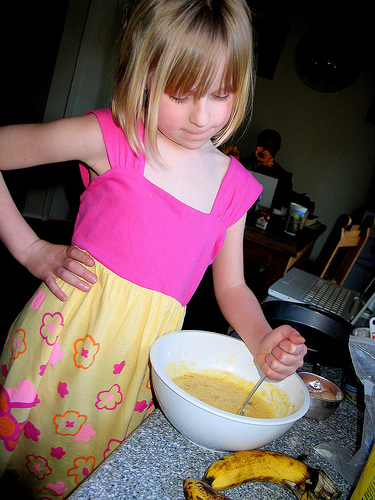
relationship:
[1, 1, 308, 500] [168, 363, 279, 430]
girl making food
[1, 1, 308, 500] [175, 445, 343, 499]
girl making food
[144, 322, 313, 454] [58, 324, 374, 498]
bowl on counter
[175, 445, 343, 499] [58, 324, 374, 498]
food on counter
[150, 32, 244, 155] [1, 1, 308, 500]
face of girl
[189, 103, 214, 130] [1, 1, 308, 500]
nose of girl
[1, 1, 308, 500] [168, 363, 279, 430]
girl mixing food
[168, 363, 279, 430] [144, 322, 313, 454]
food in bowl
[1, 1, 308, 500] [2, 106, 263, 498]
girl wearing dress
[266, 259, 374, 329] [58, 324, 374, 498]
laptop on counter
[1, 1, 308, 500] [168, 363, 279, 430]
girl stirring food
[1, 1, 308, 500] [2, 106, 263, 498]
girl in dress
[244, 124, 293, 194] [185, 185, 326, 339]
person at desk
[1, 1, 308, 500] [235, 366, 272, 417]
girl has utensil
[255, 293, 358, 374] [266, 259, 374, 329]
pan by laptop